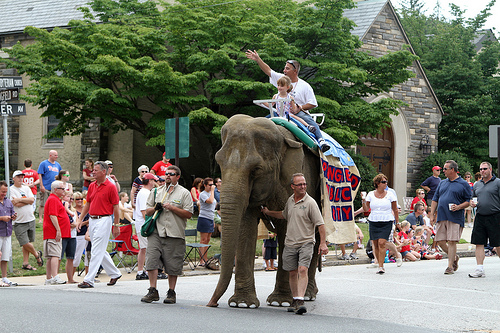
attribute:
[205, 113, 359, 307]
elephant — walking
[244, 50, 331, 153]
man — waving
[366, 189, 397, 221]
blouse — white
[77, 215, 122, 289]
pants — white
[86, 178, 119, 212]
shirt — red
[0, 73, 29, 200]
signs — black, white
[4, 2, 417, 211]
tree — large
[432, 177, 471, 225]
shirt — blue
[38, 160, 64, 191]
shirt — blue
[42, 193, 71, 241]
shirt — red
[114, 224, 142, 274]
chair — red